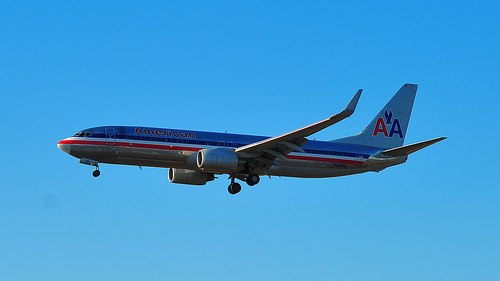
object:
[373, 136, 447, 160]
wing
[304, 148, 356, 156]
windows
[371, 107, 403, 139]
logo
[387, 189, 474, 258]
sky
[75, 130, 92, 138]
windows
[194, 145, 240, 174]
turbine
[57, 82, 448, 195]
airplane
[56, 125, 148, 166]
front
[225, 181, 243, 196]
wheel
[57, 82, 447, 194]
carrier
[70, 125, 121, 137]
cockpit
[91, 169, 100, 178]
small wheel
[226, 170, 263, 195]
landing gear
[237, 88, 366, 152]
wing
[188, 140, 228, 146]
window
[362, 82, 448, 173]
tail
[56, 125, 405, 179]
fuselage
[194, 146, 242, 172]
engine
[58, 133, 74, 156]
nose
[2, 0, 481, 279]
sky